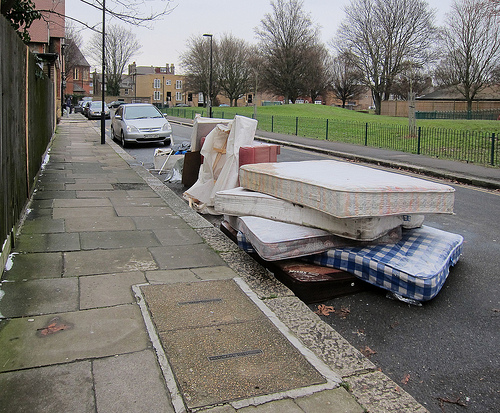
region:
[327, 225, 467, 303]
blue and white checked mattress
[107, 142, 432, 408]
wide granite curb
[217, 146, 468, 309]
stack of mattresses in the road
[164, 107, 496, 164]
wrought iron fence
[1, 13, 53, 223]
wooden privacy fence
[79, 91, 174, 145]
cars parked along the road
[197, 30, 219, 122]
black street light on opposite curb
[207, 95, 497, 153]
grassy park area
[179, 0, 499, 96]
trees have lost their leaves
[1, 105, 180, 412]
staggered slabs walkway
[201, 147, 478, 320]
Mattresses are next to a sidewalk.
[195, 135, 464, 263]
The color of three mattresses is white.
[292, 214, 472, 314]
A mattress's colors are blue and white.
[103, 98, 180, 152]
A car is parked next to a sidewalk.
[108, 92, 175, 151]
The color of a car is white.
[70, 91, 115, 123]
Vehicles are parked in the background.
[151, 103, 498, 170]
A long fence is next to a sidewalk.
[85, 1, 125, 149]
A dark pole is next to a vehicle.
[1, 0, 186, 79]
Branches are hanging over a sidewalk.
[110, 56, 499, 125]
Orange buildings are in the background.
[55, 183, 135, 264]
Concrete squares on sidewalk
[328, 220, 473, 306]
Blue and white mattress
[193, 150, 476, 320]
Stack of mattresses on the street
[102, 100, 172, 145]
Car parked beside the curb on a street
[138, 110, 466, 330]
Garbage piled on the street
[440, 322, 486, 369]
Dark grey surface of the street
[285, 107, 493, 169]
Fence on the side of a street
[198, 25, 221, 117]
Light pole on the side of the street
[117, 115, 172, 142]
Front grill of a car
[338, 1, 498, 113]
Trees without leaves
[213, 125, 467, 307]
Mattresses on the street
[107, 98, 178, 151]
Car parked at the curb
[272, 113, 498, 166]
Fence in front of grass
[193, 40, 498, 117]
Bare trees in background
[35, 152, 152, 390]
Irregular cement blocks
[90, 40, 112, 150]
Pole at edge of sidewalkl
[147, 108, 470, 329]
Discarded houseware at the curb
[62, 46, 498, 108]
Buildings in the background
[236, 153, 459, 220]
Mattress on top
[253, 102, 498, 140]
Green grass in a park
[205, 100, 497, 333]
Stack of mattresses on side of road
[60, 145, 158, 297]
Groups of block on the sidewalk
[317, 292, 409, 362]
Dry leaves on the pavement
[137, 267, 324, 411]
Opening going under the road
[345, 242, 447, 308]
Checkered blue and white mattress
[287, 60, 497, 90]
Group of trees inside fence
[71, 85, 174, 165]
Cars parked by the sidewalk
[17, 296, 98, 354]
Stain on the sidewalk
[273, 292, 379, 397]
Old and weathered pavement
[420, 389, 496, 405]
Dry stick on the road